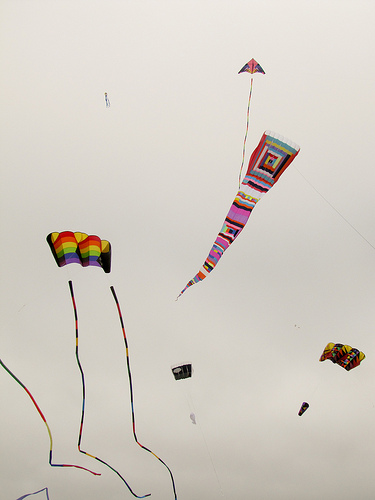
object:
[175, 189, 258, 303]
tail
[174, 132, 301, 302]
kite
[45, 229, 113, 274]
kite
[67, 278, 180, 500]
two tails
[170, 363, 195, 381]
kite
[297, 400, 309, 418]
windsock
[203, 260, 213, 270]
lines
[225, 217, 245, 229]
stripe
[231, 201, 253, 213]
stripe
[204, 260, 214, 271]
stripe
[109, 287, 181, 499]
tail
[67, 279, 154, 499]
tail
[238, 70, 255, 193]
strings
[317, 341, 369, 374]
kite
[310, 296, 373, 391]
right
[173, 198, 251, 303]
pattern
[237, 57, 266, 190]
lantern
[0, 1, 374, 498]
clouds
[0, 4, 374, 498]
air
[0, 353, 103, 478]
ribbon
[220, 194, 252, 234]
color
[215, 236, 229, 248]
color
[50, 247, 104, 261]
stripes